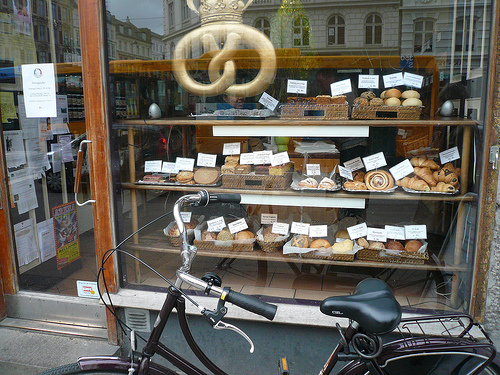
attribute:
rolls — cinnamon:
[351, 156, 387, 194]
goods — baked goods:
[194, 150, 342, 252]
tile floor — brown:
[99, 251, 456, 280]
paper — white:
[20, 60, 57, 120]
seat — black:
[322, 271, 402, 331]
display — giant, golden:
[168, 0, 276, 95]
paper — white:
[364, 150, 389, 171]